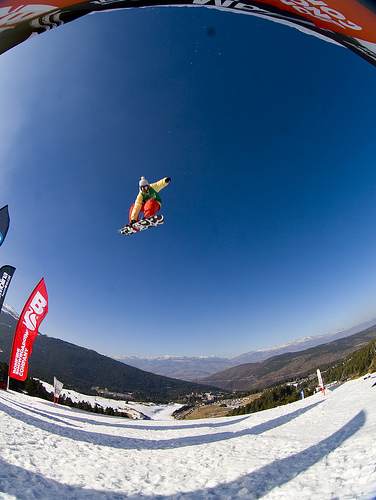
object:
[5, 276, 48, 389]
flag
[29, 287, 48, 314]
letters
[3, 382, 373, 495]
snow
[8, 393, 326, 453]
shadows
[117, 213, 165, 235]
snowboard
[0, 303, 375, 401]
mountains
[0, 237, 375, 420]
distance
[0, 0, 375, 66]
flags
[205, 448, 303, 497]
footprints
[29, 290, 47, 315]
b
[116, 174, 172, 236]
snowboarder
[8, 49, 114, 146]
air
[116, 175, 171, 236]
trick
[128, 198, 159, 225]
pants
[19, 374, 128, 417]
trees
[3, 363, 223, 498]
path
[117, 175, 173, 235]
outfit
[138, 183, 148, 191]
googles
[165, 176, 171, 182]
glove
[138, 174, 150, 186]
beanie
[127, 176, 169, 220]
jacket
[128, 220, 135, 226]
hand